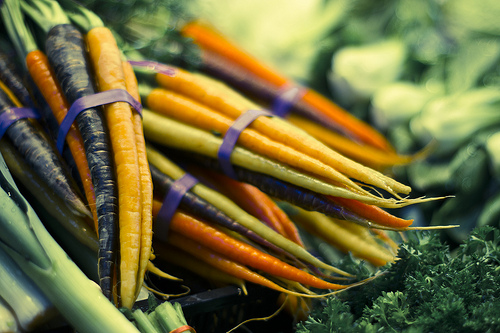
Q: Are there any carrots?
A: Yes, there is a carrot.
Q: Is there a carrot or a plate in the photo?
A: Yes, there is a carrot.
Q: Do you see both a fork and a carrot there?
A: No, there is a carrot but no forks.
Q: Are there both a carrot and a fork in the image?
A: No, there is a carrot but no forks.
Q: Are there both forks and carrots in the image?
A: No, there is a carrot but no forks.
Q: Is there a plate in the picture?
A: No, there are no plates.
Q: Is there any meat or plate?
A: No, there are no plates or meat.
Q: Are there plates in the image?
A: No, there are no plates.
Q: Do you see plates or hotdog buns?
A: No, there are no plates or hotdog buns.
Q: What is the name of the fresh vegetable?
A: The vegetable is parsley.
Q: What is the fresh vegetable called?
A: The vegetable is parsley.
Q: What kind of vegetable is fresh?
A: The vegetable is parsley.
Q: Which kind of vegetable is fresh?
A: The vegetable is parsley.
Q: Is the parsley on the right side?
A: Yes, the parsley is on the right of the image.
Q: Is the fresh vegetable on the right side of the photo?
A: Yes, the parsley is on the right of the image.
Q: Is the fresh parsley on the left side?
A: No, the parsley is on the right of the image.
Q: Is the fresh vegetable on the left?
A: No, the parsley is on the right of the image.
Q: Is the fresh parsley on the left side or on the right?
A: The parsley is on the right of the image.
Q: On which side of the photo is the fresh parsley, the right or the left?
A: The parsley is on the right of the image.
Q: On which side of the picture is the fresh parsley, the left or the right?
A: The parsley is on the right of the image.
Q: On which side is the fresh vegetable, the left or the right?
A: The parsley is on the right of the image.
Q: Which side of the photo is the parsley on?
A: The parsley is on the right of the image.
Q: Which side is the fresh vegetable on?
A: The parsley is on the right of the image.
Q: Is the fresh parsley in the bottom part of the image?
A: Yes, the parsley is in the bottom of the image.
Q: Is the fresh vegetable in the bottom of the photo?
A: Yes, the parsley is in the bottom of the image.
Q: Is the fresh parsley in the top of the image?
A: No, the parsley is in the bottom of the image.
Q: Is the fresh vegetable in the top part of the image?
A: No, the parsley is in the bottom of the image.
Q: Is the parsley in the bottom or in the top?
A: The parsley is in the bottom of the image.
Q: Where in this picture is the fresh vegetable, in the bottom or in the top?
A: The parsley is in the bottom of the image.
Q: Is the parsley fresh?
A: Yes, the parsley is fresh.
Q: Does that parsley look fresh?
A: Yes, the parsley is fresh.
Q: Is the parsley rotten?
A: No, the parsley is fresh.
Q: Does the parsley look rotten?
A: No, the parsley is fresh.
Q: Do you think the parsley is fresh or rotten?
A: The parsley is fresh.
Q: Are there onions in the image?
A: Yes, there are onions.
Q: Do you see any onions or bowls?
A: Yes, there are onions.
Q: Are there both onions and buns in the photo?
A: No, there are onions but no buns.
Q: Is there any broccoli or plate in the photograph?
A: No, there are no broccoli or plates.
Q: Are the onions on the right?
A: No, the onions are on the left of the image.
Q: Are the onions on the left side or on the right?
A: The onions are on the left of the image.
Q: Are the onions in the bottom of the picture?
A: Yes, the onions are in the bottom of the image.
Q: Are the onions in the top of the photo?
A: No, the onions are in the bottom of the image.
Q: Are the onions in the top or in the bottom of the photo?
A: The onions are in the bottom of the image.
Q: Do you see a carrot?
A: Yes, there is a carrot.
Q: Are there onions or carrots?
A: Yes, there is a carrot.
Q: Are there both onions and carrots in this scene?
A: Yes, there are both a carrot and an onion.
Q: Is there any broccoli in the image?
A: No, there is no broccoli.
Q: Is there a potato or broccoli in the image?
A: No, there are no broccoli or potatoes.